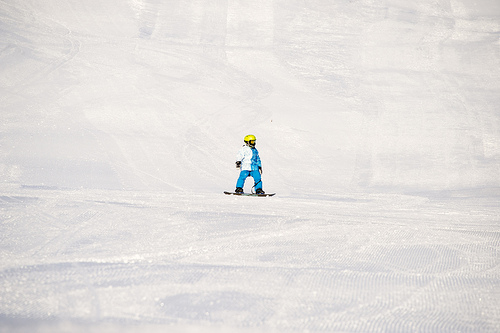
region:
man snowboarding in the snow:
[210, 121, 280, 203]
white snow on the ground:
[351, 191, 471, 296]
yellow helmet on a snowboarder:
[240, 131, 262, 141]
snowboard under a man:
[220, 185, 282, 200]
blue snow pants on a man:
[235, 170, 268, 187]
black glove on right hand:
[237, 159, 244, 172]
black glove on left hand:
[253, 161, 265, 171]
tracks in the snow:
[203, 204, 290, 224]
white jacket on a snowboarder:
[237, 140, 252, 176]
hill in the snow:
[309, 10, 464, 190]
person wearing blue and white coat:
[222, 122, 293, 211]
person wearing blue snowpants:
[226, 123, 309, 213]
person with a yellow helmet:
[206, 108, 273, 155]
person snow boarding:
[218, 123, 290, 212]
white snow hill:
[49, 15, 222, 199]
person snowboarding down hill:
[174, 80, 329, 225]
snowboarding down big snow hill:
[161, 57, 334, 232]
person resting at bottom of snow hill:
[127, 55, 367, 275]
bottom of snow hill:
[43, 188, 235, 300]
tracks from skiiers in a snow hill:
[47, 10, 434, 131]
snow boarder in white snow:
[228, 114, 275, 201]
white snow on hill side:
[35, 36, 92, 123]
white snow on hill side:
[109, 48, 164, 97]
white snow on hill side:
[33, 127, 83, 201]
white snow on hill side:
[109, 111, 177, 161]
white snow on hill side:
[70, 206, 141, 252]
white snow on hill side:
[143, 227, 220, 285]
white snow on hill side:
[293, 257, 342, 304]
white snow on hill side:
[339, 140, 423, 190]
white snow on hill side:
[304, 65, 372, 123]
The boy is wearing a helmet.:
[228, 128, 274, 195]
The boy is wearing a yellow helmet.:
[228, 131, 272, 200]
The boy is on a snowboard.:
[220, 136, 278, 200]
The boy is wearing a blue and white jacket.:
[223, 131, 277, 198]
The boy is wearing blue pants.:
[223, 131, 275, 199]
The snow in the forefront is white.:
[154, 277, 278, 331]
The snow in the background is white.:
[322, 17, 417, 77]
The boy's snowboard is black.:
[216, 185, 281, 200]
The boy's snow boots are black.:
[218, 183, 277, 197]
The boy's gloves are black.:
[233, 158, 242, 170]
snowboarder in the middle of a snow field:
[224, 128, 277, 198]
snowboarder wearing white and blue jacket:
[237, 143, 264, 172]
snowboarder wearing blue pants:
[236, 168, 265, 193]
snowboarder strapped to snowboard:
[223, 184, 275, 198]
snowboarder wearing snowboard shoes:
[231, 182, 265, 194]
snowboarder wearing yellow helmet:
[240, 132, 257, 144]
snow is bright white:
[6, 3, 493, 324]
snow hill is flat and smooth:
[1, 2, 496, 323]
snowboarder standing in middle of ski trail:
[220, 130, 279, 205]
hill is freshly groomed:
[4, 0, 495, 325]